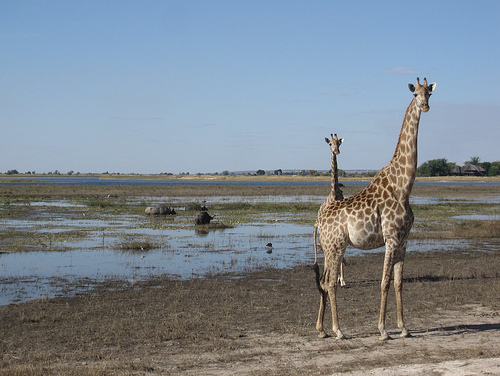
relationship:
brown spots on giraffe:
[378, 176, 404, 216] [311, 72, 437, 346]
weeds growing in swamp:
[22, 227, 94, 249] [1, 180, 497, 277]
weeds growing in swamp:
[82, 202, 145, 220] [1, 180, 497, 277]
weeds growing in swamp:
[1, 201, 61, 223] [1, 180, 497, 277]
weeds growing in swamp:
[227, 206, 277, 226] [1, 180, 497, 277]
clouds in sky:
[290, 70, 499, 167] [0, 0, 499, 172]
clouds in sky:
[373, 55, 429, 78] [45, 28, 307, 112]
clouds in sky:
[3, 117, 126, 170] [3, 4, 498, 157]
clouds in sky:
[253, 80, 381, 157] [3, 4, 498, 157]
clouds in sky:
[432, 89, 499, 157] [3, 4, 498, 157]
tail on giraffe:
[307, 219, 322, 272] [311, 72, 437, 346]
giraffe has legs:
[290, 80, 444, 349] [375, 231, 411, 346]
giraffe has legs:
[290, 80, 444, 349] [303, 245, 357, 351]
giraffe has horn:
[311, 72, 437, 346] [413, 75, 420, 85]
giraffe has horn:
[311, 72, 437, 346] [422, 73, 429, 85]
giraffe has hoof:
[305, 77, 439, 354] [399, 325, 412, 340]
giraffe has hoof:
[305, 77, 439, 354] [376, 329, 391, 344]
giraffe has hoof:
[316, 132, 358, 192] [333, 331, 349, 341]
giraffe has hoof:
[316, 132, 358, 192] [314, 332, 330, 341]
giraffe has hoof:
[316, 132, 358, 192] [337, 279, 351, 287]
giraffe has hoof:
[337, 72, 456, 334] [332, 318, 349, 340]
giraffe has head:
[326, 163, 345, 210] [323, 133, 344, 168]